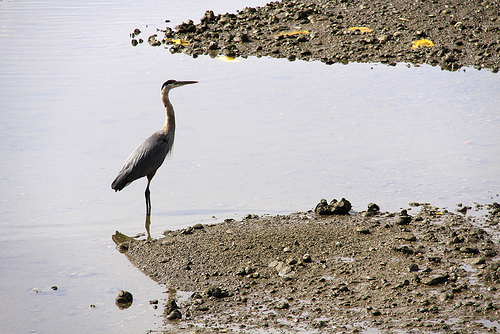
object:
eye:
[171, 80, 175, 82]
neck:
[162, 90, 176, 130]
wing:
[110, 132, 173, 193]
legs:
[144, 175, 152, 239]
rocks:
[131, 38, 139, 47]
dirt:
[114, 197, 499, 334]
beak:
[178, 81, 199, 86]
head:
[163, 79, 199, 89]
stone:
[282, 245, 292, 254]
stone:
[282, 244, 291, 254]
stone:
[300, 252, 310, 260]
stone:
[366, 244, 376, 253]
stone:
[191, 222, 204, 231]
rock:
[164, 308, 182, 320]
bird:
[109, 79, 199, 237]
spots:
[412, 38, 433, 48]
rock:
[90, 304, 97, 307]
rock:
[393, 31, 403, 37]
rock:
[300, 251, 312, 262]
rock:
[283, 254, 301, 265]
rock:
[244, 264, 252, 276]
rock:
[403, 263, 421, 273]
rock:
[407, 263, 421, 274]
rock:
[192, 223, 205, 230]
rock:
[224, 228, 234, 235]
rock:
[384, 222, 391, 229]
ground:
[115, 196, 499, 334]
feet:
[146, 234, 153, 241]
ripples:
[0, 0, 500, 334]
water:
[0, 1, 500, 334]